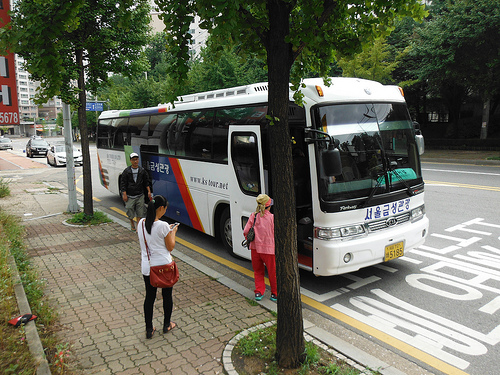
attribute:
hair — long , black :
[141, 197, 159, 241]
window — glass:
[98, 118, 113, 147]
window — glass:
[330, 107, 407, 187]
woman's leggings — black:
[144, 273, 173, 333]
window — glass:
[127, 116, 150, 149]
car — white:
[47, 147, 84, 163]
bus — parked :
[94, 77, 431, 282]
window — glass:
[173, 108, 214, 160]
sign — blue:
[65, 106, 145, 148]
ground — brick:
[73, 271, 138, 356]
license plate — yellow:
[375, 239, 407, 267]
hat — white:
[125, 153, 150, 158]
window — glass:
[229, 127, 263, 196]